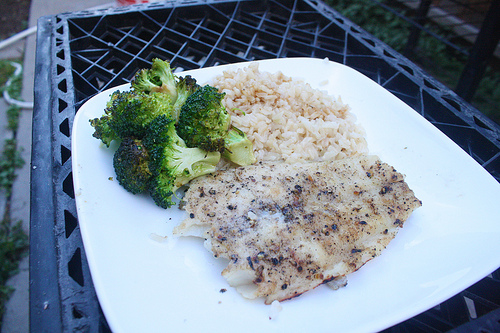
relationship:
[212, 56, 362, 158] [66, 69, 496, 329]
rice on plate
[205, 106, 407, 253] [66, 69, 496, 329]
fish on plate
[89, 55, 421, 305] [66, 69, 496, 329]
food on plate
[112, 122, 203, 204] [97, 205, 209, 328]
brocolli on plate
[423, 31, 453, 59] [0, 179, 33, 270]
bushes in ground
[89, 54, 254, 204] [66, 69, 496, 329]
broccoli on plate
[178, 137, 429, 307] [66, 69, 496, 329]
chicken on plate